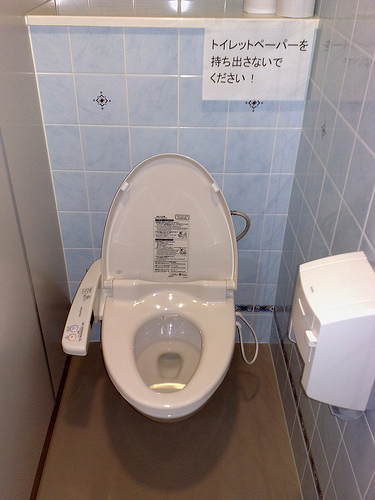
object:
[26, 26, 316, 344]
wall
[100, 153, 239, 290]
lid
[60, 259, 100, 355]
armrest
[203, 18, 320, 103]
sign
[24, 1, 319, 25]
shelf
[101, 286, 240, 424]
toilet seat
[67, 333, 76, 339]
button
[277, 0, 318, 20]
toilet paper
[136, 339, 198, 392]
water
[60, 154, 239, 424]
toilet